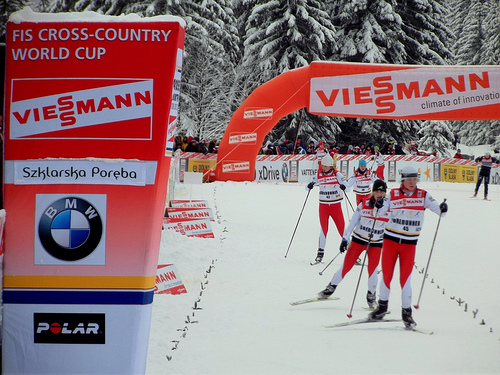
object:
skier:
[367, 162, 447, 329]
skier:
[319, 177, 390, 310]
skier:
[307, 154, 347, 265]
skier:
[342, 160, 384, 212]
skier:
[472, 153, 498, 198]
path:
[177, 180, 498, 373]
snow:
[456, 362, 499, 374]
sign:
[218, 60, 498, 183]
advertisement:
[162, 217, 217, 240]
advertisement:
[153, 266, 187, 296]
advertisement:
[34, 192, 107, 266]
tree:
[233, 1, 405, 161]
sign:
[170, 199, 210, 208]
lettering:
[256, 165, 278, 180]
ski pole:
[418, 197, 447, 309]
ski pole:
[347, 206, 381, 319]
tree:
[399, 1, 483, 157]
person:
[294, 140, 306, 157]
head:
[296, 141, 300, 146]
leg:
[370, 250, 395, 318]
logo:
[35, 198, 105, 260]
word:
[37, 321, 101, 336]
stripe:
[2, 290, 154, 305]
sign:
[0, 10, 186, 374]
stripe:
[1, 275, 157, 290]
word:
[22, 164, 86, 182]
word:
[91, 164, 137, 179]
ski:
[325, 316, 401, 328]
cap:
[358, 159, 367, 166]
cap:
[321, 154, 334, 167]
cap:
[372, 179, 387, 192]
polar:
[34, 311, 106, 346]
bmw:
[41, 197, 101, 219]